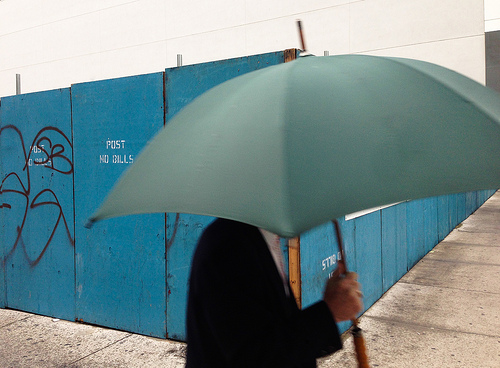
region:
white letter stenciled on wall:
[105, 138, 110, 149]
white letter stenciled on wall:
[110, 139, 115, 150]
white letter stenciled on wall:
[114, 138, 121, 149]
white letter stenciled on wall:
[119, 139, 126, 147]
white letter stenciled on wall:
[98, 151, 105, 163]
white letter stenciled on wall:
[103, 153, 110, 163]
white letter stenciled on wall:
[111, 153, 117, 164]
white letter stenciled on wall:
[321, 258, 330, 269]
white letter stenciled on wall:
[121, 153, 128, 164]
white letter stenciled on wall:
[129, 151, 136, 164]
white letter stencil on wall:
[105, 138, 112, 150]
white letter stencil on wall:
[110, 137, 117, 149]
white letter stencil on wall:
[113, 139, 120, 151]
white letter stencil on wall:
[117, 138, 127, 148]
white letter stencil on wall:
[97, 151, 105, 163]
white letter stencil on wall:
[103, 153, 110, 163]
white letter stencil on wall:
[110, 153, 117, 163]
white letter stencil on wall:
[121, 152, 129, 166]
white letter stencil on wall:
[127, 152, 136, 163]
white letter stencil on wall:
[321, 257, 327, 271]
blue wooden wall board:
[0, 88, 79, 324]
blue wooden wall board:
[70, 75, 168, 337]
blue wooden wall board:
[163, 65, 278, 344]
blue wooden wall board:
[300, 212, 352, 336]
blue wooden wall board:
[352, 211, 384, 303]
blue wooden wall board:
[378, 211, 395, 288]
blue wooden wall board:
[396, 205, 406, 278]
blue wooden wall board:
[406, 204, 421, 261]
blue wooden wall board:
[433, 201, 448, 237]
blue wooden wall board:
[457, 196, 469, 226]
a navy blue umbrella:
[85, 43, 499, 227]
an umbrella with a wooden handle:
[90, 20, 495, 366]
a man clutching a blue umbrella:
[91, 52, 496, 365]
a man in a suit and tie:
[181, 216, 344, 366]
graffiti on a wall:
[0, 125, 83, 280]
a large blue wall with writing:
[72, 72, 167, 341]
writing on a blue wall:
[91, 136, 135, 165]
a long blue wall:
[1, 58, 499, 325]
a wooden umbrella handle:
[353, 329, 371, 364]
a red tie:
[268, 230, 289, 285]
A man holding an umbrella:
[78, 15, 498, 359]